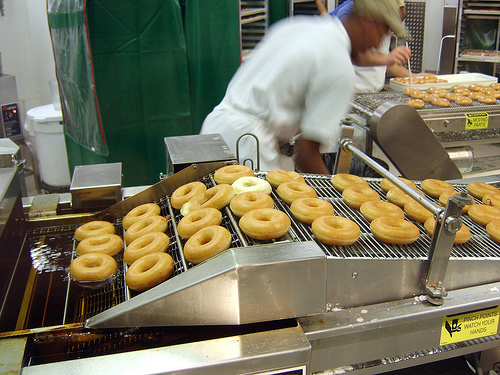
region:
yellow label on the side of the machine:
[438, 310, 498, 342]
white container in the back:
[19, 106, 69, 185]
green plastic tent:
[44, 1, 240, 184]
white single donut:
[233, 175, 272, 194]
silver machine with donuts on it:
[1, 138, 498, 373]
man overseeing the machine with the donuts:
[201, 0, 408, 181]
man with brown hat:
[201, 1, 408, 174]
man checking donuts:
[333, 1, 413, 93]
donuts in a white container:
[389, 73, 496, 89]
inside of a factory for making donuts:
[0, 0, 497, 372]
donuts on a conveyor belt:
[67, 155, 497, 292]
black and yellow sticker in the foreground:
[435, 312, 495, 352]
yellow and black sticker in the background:
[460, 108, 492, 134]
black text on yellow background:
[459, 310, 495, 337]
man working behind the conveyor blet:
[196, 8, 416, 164]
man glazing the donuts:
[336, 1, 416, 101]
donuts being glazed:
[385, 54, 494, 105]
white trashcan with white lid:
[28, 102, 83, 196]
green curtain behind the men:
[64, 0, 244, 176]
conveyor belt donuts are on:
[109, 175, 499, 279]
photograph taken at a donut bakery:
[7, 13, 484, 364]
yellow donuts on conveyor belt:
[66, 168, 491, 297]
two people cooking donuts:
[206, 0, 448, 165]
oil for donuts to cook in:
[6, 201, 119, 341]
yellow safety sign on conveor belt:
[430, 301, 498, 346]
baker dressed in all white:
[197, 17, 359, 166]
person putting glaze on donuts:
[353, 34, 496, 111]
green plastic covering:
[53, 3, 238, 190]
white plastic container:
[17, 85, 80, 182]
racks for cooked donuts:
[447, 2, 499, 78]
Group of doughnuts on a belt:
[197, 148, 322, 265]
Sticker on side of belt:
[442, 305, 498, 363]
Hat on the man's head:
[345, 5, 425, 65]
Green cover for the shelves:
[45, 0, 274, 182]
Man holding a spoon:
[400, 42, 434, 104]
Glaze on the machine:
[344, 279, 381, 331]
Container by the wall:
[22, 86, 97, 204]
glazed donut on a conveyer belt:
[311, 209, 361, 249]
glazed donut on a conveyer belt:
[65, 250, 120, 286]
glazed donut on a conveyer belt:
[75, 233, 125, 259]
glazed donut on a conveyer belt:
[70, 215, 114, 245]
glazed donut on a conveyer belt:
[120, 248, 175, 288]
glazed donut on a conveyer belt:
[119, 231, 169, 266]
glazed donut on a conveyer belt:
[182, 220, 234, 265]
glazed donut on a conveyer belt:
[237, 207, 292, 245]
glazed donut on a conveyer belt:
[225, 188, 280, 218]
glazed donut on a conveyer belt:
[287, 196, 339, 225]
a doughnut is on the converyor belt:
[75, 250, 113, 280]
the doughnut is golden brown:
[71, 252, 113, 280]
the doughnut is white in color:
[234, 176, 271, 198]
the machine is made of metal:
[1, 140, 497, 370]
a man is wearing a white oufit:
[206, 12, 354, 157]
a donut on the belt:
[243, 215, 289, 267]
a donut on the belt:
[328, 213, 353, 244]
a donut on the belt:
[377, 217, 404, 237]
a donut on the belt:
[304, 193, 321, 208]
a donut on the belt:
[125, 258, 162, 296]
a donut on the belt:
[128, 233, 162, 252]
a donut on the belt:
[159, 187, 199, 206]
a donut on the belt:
[133, 212, 167, 239]